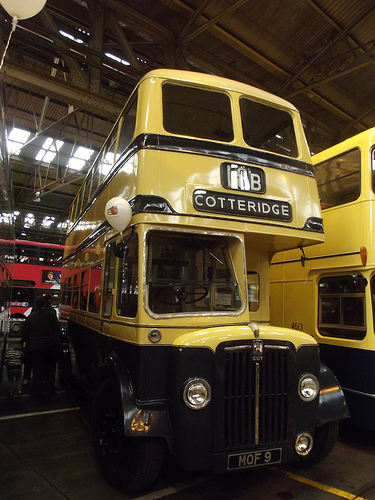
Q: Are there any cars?
A: No, there are no cars.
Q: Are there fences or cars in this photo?
A: No, there are no cars or fences.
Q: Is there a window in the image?
A: Yes, there is a window.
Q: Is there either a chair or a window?
A: Yes, there is a window.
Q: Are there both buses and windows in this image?
A: Yes, there are both a window and a bus.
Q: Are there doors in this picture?
A: No, there are no doors.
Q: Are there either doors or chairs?
A: No, there are no doors or chairs.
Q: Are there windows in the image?
A: Yes, there is a window.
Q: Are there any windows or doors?
A: Yes, there is a window.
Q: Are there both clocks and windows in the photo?
A: No, there is a window but no clocks.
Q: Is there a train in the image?
A: No, there are no trains.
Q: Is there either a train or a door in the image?
A: No, there are no trains or doors.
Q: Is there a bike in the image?
A: No, there are no bikes.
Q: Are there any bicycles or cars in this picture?
A: No, there are no bicycles or cars.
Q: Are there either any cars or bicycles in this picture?
A: No, there are no bicycles or cars.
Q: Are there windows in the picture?
A: Yes, there is a window.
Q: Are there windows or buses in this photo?
A: Yes, there is a window.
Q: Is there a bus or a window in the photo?
A: Yes, there is a window.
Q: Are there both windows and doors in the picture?
A: No, there is a window but no doors.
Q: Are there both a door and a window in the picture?
A: No, there is a window but no doors.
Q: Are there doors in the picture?
A: No, there are no doors.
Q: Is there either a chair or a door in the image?
A: No, there are no doors or chairs.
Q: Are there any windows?
A: Yes, there is a window.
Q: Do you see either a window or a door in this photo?
A: Yes, there is a window.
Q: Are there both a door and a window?
A: No, there is a window but no doors.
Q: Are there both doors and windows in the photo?
A: No, there is a window but no doors.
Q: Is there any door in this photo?
A: No, there are no doors.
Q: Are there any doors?
A: No, there are no doors.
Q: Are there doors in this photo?
A: No, there are no doors.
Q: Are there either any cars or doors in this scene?
A: No, there are no doors or cars.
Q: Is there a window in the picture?
A: Yes, there is a window.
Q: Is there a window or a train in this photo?
A: Yes, there is a window.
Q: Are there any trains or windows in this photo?
A: Yes, there is a window.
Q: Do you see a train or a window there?
A: Yes, there is a window.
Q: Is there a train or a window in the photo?
A: Yes, there is a window.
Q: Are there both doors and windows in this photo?
A: No, there is a window but no doors.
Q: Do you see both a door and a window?
A: No, there is a window but no doors.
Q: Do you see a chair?
A: No, there are no chairs.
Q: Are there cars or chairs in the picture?
A: No, there are no chairs or cars.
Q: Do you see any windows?
A: Yes, there is a window.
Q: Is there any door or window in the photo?
A: Yes, there is a window.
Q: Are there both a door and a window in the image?
A: No, there is a window but no doors.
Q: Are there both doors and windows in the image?
A: No, there is a window but no doors.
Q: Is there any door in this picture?
A: No, there are no doors.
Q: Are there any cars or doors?
A: No, there are no doors or cars.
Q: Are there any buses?
A: Yes, there is a bus.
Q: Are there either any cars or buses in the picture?
A: Yes, there is a bus.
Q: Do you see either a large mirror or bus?
A: Yes, there is a large bus.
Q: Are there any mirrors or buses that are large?
A: Yes, the bus is large.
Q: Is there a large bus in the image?
A: Yes, there is a large bus.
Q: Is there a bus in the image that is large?
A: Yes, there is a bus that is large.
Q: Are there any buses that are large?
A: Yes, there is a bus that is large.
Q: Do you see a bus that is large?
A: Yes, there is a bus that is large.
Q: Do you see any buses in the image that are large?
A: Yes, there is a bus that is large.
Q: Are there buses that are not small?
A: Yes, there is a large bus.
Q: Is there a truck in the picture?
A: No, there are no trucks.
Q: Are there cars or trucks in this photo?
A: No, there are no trucks or cars.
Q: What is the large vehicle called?
A: The vehicle is a bus.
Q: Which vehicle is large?
A: The vehicle is a bus.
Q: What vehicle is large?
A: The vehicle is a bus.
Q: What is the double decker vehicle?
A: The vehicle is a bus.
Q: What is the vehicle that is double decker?
A: The vehicle is a bus.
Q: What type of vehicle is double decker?
A: The vehicle is a bus.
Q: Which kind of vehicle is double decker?
A: The vehicle is a bus.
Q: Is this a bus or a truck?
A: This is a bus.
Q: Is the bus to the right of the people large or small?
A: The bus is large.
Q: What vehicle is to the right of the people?
A: The vehicle is a bus.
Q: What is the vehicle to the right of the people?
A: The vehicle is a bus.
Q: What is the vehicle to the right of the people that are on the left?
A: The vehicle is a bus.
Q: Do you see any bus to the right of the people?
A: Yes, there is a bus to the right of the people.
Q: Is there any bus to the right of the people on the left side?
A: Yes, there is a bus to the right of the people.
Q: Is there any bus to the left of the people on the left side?
A: No, the bus is to the right of the people.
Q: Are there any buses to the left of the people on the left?
A: No, the bus is to the right of the people.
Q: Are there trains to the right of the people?
A: No, there is a bus to the right of the people.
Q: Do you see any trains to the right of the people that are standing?
A: No, there is a bus to the right of the people.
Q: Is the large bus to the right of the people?
A: Yes, the bus is to the right of the people.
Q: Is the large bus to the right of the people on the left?
A: Yes, the bus is to the right of the people.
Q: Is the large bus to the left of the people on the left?
A: No, the bus is to the right of the people.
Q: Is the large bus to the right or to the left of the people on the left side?
A: The bus is to the right of the people.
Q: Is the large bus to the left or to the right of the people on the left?
A: The bus is to the right of the people.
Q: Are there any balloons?
A: Yes, there is a balloon.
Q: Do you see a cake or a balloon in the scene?
A: Yes, there is a balloon.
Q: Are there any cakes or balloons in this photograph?
A: Yes, there is a balloon.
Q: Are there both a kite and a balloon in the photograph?
A: No, there is a balloon but no kites.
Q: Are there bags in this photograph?
A: No, there are no bags.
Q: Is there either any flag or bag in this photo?
A: No, there are no bags or flags.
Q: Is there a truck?
A: No, there are no trucks.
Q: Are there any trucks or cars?
A: No, there are no trucks or cars.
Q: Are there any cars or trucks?
A: No, there are no trucks or cars.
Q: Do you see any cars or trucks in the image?
A: No, there are no trucks or cars.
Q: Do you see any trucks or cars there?
A: No, there are no trucks or cars.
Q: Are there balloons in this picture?
A: Yes, there is a balloon.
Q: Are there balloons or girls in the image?
A: Yes, there is a balloon.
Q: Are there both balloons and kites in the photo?
A: No, there is a balloon but no kites.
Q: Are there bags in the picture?
A: No, there are no bags.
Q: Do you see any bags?
A: No, there are no bags.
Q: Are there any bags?
A: No, there are no bags.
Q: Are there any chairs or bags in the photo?
A: No, there are no bags or chairs.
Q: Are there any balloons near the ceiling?
A: Yes, there is a balloon near the ceiling.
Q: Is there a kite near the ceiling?
A: No, there is a balloon near the ceiling.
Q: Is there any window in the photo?
A: Yes, there is a window.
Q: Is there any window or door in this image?
A: Yes, there is a window.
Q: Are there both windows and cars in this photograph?
A: No, there is a window but no cars.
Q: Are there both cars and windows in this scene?
A: No, there is a window but no cars.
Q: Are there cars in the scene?
A: No, there are no cars.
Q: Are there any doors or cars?
A: No, there are no cars or doors.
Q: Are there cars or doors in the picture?
A: No, there are no cars or doors.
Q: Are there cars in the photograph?
A: No, there are no cars.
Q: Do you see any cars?
A: No, there are no cars.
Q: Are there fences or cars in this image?
A: No, there are no cars or fences.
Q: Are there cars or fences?
A: No, there are no cars or fences.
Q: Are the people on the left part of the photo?
A: Yes, the people are on the left of the image.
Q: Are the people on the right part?
A: No, the people are on the left of the image.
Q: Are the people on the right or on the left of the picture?
A: The people are on the left of the image.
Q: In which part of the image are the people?
A: The people are on the left of the image.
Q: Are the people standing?
A: Yes, the people are standing.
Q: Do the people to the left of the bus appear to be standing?
A: Yes, the people are standing.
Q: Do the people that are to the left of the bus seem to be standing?
A: Yes, the people are standing.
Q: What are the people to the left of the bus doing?
A: The people are standing.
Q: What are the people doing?
A: The people are standing.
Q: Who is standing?
A: The people are standing.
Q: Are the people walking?
A: No, the people are standing.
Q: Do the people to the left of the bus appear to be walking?
A: No, the people are standing.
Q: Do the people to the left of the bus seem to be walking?
A: No, the people are standing.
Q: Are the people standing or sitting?
A: The people are standing.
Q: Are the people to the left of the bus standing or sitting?
A: The people are standing.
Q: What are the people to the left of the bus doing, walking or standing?
A: The people are standing.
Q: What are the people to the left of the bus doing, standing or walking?
A: The people are standing.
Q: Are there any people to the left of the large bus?
A: Yes, there are people to the left of the bus.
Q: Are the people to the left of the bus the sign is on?
A: Yes, the people are to the left of the bus.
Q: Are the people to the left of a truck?
A: No, the people are to the left of the bus.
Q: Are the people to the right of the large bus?
A: No, the people are to the left of the bus.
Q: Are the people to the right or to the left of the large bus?
A: The people are to the left of the bus.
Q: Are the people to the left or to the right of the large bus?
A: The people are to the left of the bus.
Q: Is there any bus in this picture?
A: Yes, there is a bus.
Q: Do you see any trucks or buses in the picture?
A: Yes, there is a bus.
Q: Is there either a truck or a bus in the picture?
A: Yes, there is a bus.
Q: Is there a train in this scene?
A: No, there are no trains.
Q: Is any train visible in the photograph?
A: No, there are no trains.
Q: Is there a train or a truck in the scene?
A: No, there are no trains or trucks.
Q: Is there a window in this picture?
A: Yes, there is a window.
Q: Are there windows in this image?
A: Yes, there is a window.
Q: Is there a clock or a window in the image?
A: Yes, there is a window.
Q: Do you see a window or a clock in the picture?
A: Yes, there is a window.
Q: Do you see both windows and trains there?
A: No, there is a window but no trains.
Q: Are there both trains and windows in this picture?
A: No, there is a window but no trains.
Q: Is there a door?
A: No, there are no doors.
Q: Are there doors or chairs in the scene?
A: No, there are no doors or chairs.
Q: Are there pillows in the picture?
A: No, there are no pillows.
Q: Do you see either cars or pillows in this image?
A: No, there are no pillows or cars.